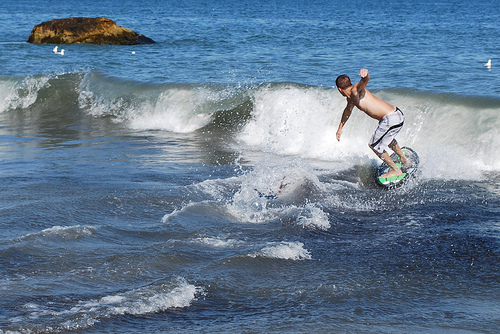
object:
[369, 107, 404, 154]
boardshorts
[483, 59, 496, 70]
bird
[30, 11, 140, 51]
rock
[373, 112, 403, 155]
trunks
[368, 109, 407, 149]
stripe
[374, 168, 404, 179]
feet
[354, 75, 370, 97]
arm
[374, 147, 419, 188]
board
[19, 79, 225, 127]
wave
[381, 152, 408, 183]
green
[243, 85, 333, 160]
wave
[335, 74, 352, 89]
hair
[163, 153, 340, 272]
caps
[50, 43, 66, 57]
birds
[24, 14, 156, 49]
formation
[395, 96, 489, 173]
wave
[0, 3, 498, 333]
ocean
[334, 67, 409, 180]
boy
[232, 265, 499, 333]
surface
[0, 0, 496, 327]
water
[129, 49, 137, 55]
seagull